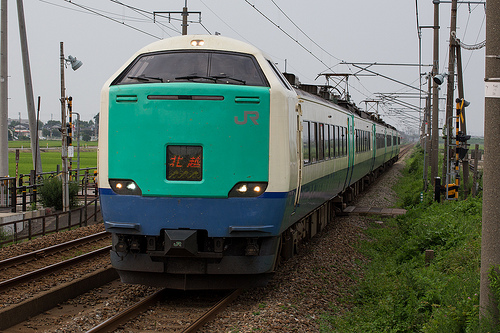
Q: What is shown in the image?
A: A Train.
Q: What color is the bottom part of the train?
A: Blue.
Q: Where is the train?
A: On the tracks.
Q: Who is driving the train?
A: The conductor.